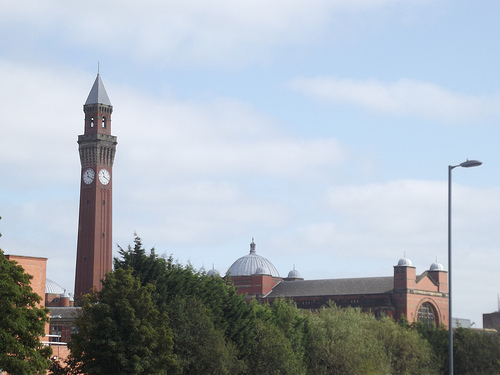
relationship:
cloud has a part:
[250, 72, 469, 136] [296, 75, 356, 106]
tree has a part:
[4, 241, 67, 374] [13, 257, 38, 315]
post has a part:
[440, 161, 486, 374] [442, 153, 484, 208]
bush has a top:
[73, 230, 228, 375] [102, 232, 172, 285]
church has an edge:
[68, 60, 449, 350] [130, 260, 466, 327]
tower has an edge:
[73, 58, 119, 312] [71, 137, 84, 307]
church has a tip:
[68, 60, 449, 350] [79, 57, 114, 108]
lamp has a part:
[440, 161, 486, 374] [442, 153, 484, 208]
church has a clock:
[68, 60, 449, 350] [78, 167, 95, 186]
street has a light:
[445, 158, 480, 371] [440, 161, 486, 374]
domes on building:
[223, 239, 448, 281] [108, 232, 498, 374]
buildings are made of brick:
[108, 232, 498, 374] [388, 279, 446, 326]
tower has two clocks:
[73, 58, 119, 312] [80, 161, 112, 187]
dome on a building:
[217, 239, 279, 278] [108, 232, 498, 374]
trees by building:
[3, 251, 499, 370] [108, 232, 498, 374]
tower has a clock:
[73, 58, 119, 312] [78, 167, 95, 186]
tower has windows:
[73, 58, 119, 312] [86, 115, 107, 129]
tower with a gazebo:
[73, 58, 119, 312] [78, 106, 118, 143]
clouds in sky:
[127, 10, 490, 150] [131, 17, 486, 148]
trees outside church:
[3, 251, 499, 370] [75, 66, 450, 370]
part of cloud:
[3, 6, 475, 279] [250, 72, 469, 136]